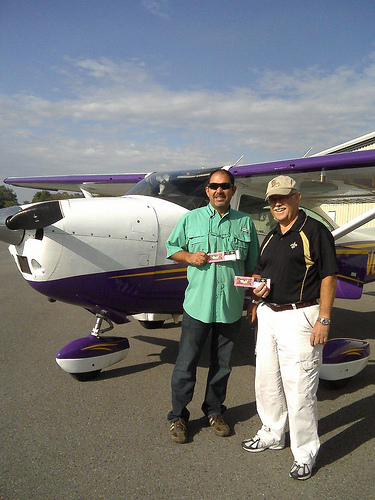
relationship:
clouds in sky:
[0, 49, 375, 183] [0, 0, 373, 174]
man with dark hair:
[164, 168, 260, 445] [202, 168, 236, 189]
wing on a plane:
[240, 153, 373, 196] [44, 127, 368, 397]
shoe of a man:
[192, 395, 236, 448] [152, 143, 259, 318]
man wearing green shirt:
[163, 163, 257, 438] [166, 198, 258, 327]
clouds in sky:
[77, 57, 156, 95] [0, 0, 373, 174]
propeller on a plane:
[3, 189, 72, 237] [1, 149, 374, 399]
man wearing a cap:
[245, 172, 337, 482] [261, 174, 300, 199]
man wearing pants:
[245, 172, 337, 482] [252, 297, 320, 465]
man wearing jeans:
[164, 168, 260, 445] [165, 308, 240, 423]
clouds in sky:
[0, 49, 375, 183] [4, 5, 373, 160]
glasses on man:
[207, 182, 233, 189] [158, 160, 268, 399]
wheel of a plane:
[50, 329, 133, 383] [3, 99, 371, 372]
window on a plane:
[126, 169, 218, 208] [1, 149, 374, 399]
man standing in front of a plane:
[164, 168, 260, 445] [4, 165, 203, 339]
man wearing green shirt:
[164, 168, 260, 445] [164, 201, 259, 324]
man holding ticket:
[241, 174, 337, 481] [231, 272, 273, 289]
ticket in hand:
[231, 272, 273, 289] [249, 273, 272, 301]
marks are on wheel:
[84, 342, 120, 350] [31, 313, 151, 423]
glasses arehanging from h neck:
[204, 215, 242, 240] [212, 209, 229, 218]